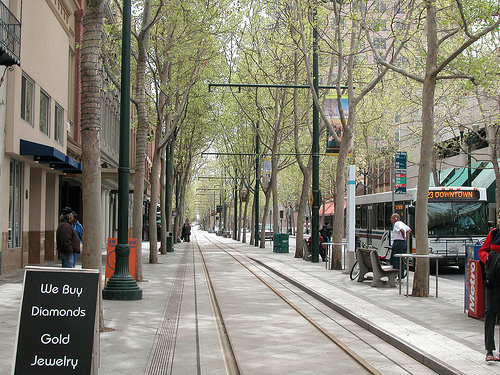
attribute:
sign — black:
[13, 267, 103, 374]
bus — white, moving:
[343, 185, 487, 279]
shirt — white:
[390, 221, 412, 241]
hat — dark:
[61, 204, 77, 218]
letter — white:
[39, 280, 54, 295]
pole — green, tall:
[100, 2, 144, 301]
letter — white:
[60, 279, 71, 297]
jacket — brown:
[54, 219, 82, 258]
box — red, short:
[463, 256, 487, 319]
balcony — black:
[0, 1, 24, 71]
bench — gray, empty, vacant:
[353, 246, 400, 289]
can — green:
[271, 230, 291, 255]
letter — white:
[28, 303, 40, 318]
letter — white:
[40, 329, 53, 345]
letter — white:
[30, 351, 40, 369]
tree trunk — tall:
[78, 0, 108, 334]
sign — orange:
[103, 235, 139, 290]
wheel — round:
[348, 259, 362, 281]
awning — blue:
[21, 136, 67, 168]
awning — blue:
[51, 150, 81, 174]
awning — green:
[469, 156, 499, 205]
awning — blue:
[63, 162, 84, 175]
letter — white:
[75, 285, 83, 300]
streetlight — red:
[210, 208, 215, 220]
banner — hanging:
[321, 94, 355, 159]